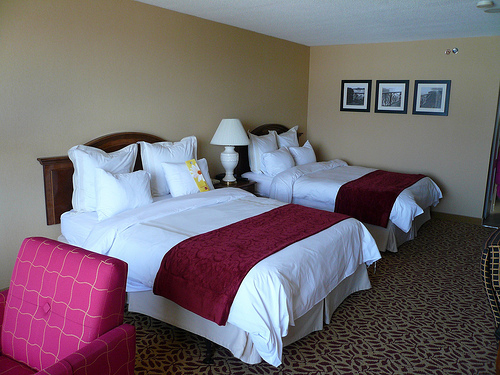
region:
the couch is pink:
[57, 285, 77, 315]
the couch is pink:
[93, 288, 98, 294]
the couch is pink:
[73, 301, 78, 318]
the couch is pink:
[67, 298, 78, 313]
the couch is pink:
[70, 317, 80, 337]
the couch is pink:
[84, 305, 95, 333]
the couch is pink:
[62, 301, 84, 329]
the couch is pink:
[79, 300, 92, 318]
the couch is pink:
[81, 306, 88, 316]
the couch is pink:
[77, 307, 92, 334]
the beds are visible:
[164, 82, 428, 361]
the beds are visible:
[190, 105, 317, 277]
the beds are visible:
[211, 143, 336, 312]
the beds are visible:
[217, 140, 277, 213]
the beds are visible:
[237, 152, 445, 338]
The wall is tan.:
[68, 45, 180, 115]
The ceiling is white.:
[293, 2, 400, 27]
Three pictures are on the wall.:
[330, 65, 462, 129]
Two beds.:
[55, 104, 448, 356]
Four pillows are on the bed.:
[52, 115, 212, 202]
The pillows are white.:
[62, 125, 219, 216]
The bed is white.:
[45, 130, 367, 340]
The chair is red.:
[0, 230, 140, 370]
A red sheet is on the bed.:
[162, 195, 382, 350]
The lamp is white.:
[203, 111, 254, 191]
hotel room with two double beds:
[10, 6, 488, 363]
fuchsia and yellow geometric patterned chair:
[0, 220, 145, 369]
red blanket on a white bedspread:
[147, 173, 341, 328]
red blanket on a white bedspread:
[332, 142, 424, 239]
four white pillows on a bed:
[66, 135, 218, 205]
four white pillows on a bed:
[243, 118, 330, 182]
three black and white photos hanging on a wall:
[327, 68, 454, 120]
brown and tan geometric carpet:
[390, 256, 475, 369]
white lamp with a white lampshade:
[210, 97, 257, 191]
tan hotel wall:
[15, 25, 225, 107]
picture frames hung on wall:
[328, 69, 457, 129]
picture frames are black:
[323, 62, 483, 149]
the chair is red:
[1, 212, 136, 365]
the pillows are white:
[67, 140, 202, 205]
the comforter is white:
[113, 214, 377, 320]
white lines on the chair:
[0, 237, 128, 362]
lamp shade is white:
[194, 110, 257, 156]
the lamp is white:
[218, 143, 255, 195]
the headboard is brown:
[22, 133, 185, 223]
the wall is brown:
[1, 0, 492, 265]